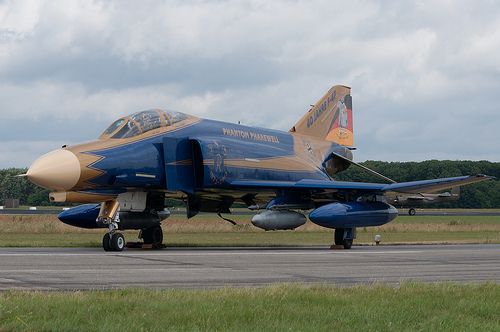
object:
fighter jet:
[14, 81, 496, 253]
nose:
[13, 147, 81, 195]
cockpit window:
[99, 109, 191, 141]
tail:
[287, 83, 353, 146]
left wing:
[238, 170, 492, 197]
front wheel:
[112, 232, 125, 250]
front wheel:
[103, 233, 110, 252]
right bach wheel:
[139, 226, 164, 247]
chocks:
[127, 241, 151, 249]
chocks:
[330, 243, 344, 249]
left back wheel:
[335, 228, 355, 250]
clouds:
[1, 0, 497, 162]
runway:
[5, 242, 500, 285]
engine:
[305, 198, 399, 229]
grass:
[0, 286, 498, 332]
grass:
[6, 212, 500, 247]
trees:
[0, 167, 48, 206]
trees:
[358, 159, 500, 205]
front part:
[19, 103, 200, 207]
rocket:
[250, 209, 306, 233]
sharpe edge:
[12, 169, 36, 184]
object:
[373, 235, 381, 247]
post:
[28, 207, 37, 211]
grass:
[2, 198, 76, 212]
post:
[62, 207, 70, 210]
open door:
[161, 134, 203, 194]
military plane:
[382, 189, 460, 215]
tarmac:
[400, 207, 499, 224]